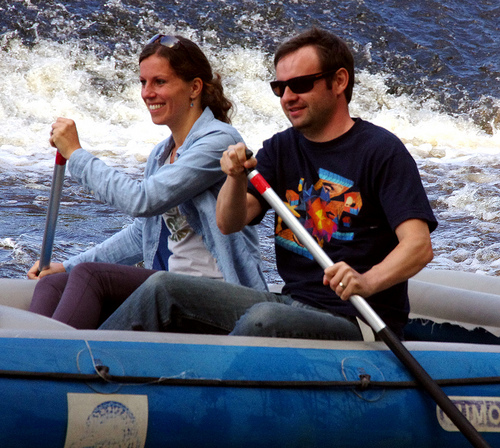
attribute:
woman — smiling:
[105, 17, 221, 139]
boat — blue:
[14, 288, 419, 430]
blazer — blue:
[82, 117, 244, 289]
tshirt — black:
[229, 132, 425, 331]